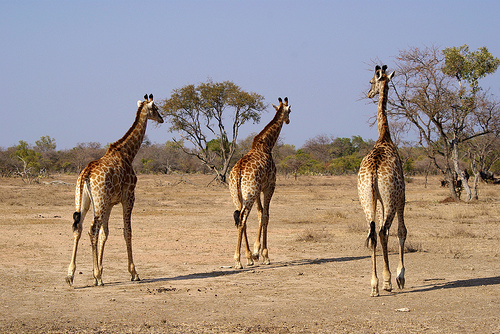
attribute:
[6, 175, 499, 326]
dirt — flattened dirt